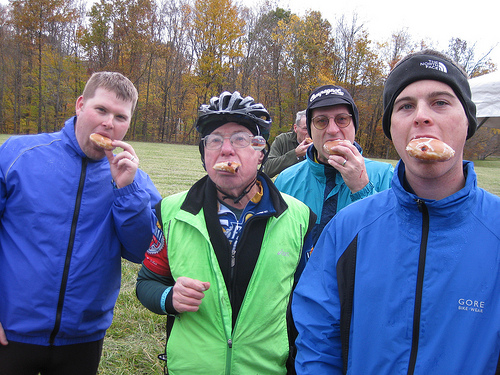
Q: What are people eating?
A: Pastries.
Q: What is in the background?
A: Trees.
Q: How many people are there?
A: Five.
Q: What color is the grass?
A: Green.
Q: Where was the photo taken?
A: Field.